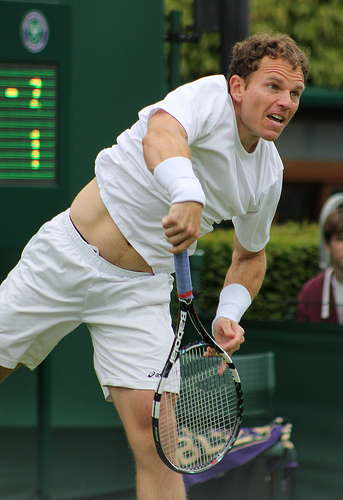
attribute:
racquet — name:
[153, 236, 244, 484]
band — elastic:
[65, 218, 115, 275]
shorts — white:
[0, 210, 175, 400]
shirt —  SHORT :
[107, 98, 288, 248]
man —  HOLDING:
[0, 26, 288, 454]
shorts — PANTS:
[0, 251, 191, 396]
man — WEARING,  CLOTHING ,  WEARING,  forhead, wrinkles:
[0, 36, 297, 486]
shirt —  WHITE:
[94, 72, 285, 270]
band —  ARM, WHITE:
[217, 281, 244, 325]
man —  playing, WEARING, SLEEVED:
[4, 34, 304, 421]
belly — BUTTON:
[84, 204, 147, 275]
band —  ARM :
[219, 280, 245, 321]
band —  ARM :
[150, 163, 204, 203]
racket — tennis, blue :
[147, 249, 257, 477]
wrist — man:
[157, 164, 204, 205]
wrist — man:
[223, 284, 246, 323]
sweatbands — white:
[222, 276, 256, 318]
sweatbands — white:
[148, 162, 201, 201]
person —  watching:
[308, 181, 332, 312]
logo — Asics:
[144, 363, 172, 383]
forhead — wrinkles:
[253, 52, 304, 83]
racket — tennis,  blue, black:
[147, 248, 246, 476]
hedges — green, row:
[212, 223, 311, 283]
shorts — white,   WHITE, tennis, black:
[0, 222, 175, 386]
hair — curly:
[244, 42, 303, 64]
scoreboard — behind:
[5, 70, 54, 182]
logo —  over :
[22, 13, 47, 50]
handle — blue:
[169, 230, 207, 299]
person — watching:
[318, 183, 332, 303]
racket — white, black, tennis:
[159, 253, 276, 475]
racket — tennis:
[156, 226, 287, 491]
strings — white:
[157, 357, 293, 479]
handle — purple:
[149, 205, 221, 316]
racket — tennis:
[144, 216, 298, 478]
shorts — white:
[13, 198, 247, 438]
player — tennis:
[20, 2, 297, 404]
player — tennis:
[17, 14, 255, 347]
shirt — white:
[96, 36, 310, 311]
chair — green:
[165, 317, 294, 481]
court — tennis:
[6, 397, 332, 492]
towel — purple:
[177, 406, 319, 497]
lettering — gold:
[179, 419, 324, 453]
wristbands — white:
[206, 281, 284, 357]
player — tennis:
[31, 24, 327, 422]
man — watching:
[294, 181, 332, 256]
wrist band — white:
[218, 281, 247, 320]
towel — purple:
[199, 427, 286, 459]